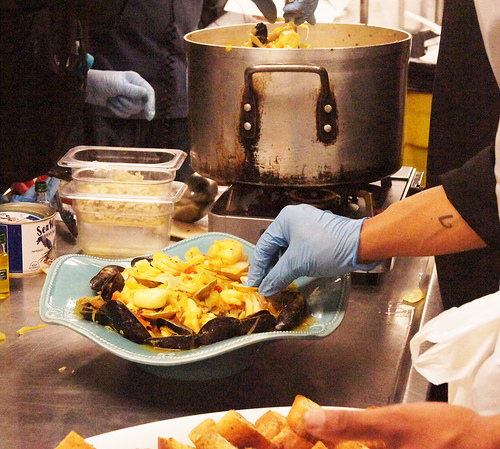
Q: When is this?
A: Daytime.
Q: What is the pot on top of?
A: A burner.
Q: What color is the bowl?
A: Blue.